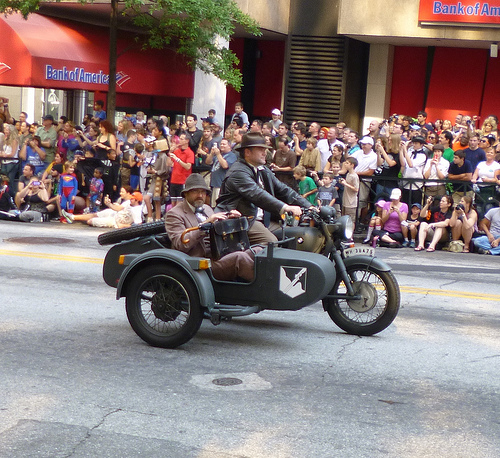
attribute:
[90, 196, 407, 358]
motorcycle — old style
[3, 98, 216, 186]
people — watching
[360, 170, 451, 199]
fenc — black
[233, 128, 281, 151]
fedora — brown 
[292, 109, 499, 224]
people — watching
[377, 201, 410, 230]
tshirt — purple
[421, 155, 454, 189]
shirt — white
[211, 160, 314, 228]
jacket — black, brown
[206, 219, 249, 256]
bag — black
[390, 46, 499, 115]
hat — orange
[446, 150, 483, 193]
shirt — blue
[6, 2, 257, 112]
tree — tall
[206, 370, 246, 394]
drain — metal